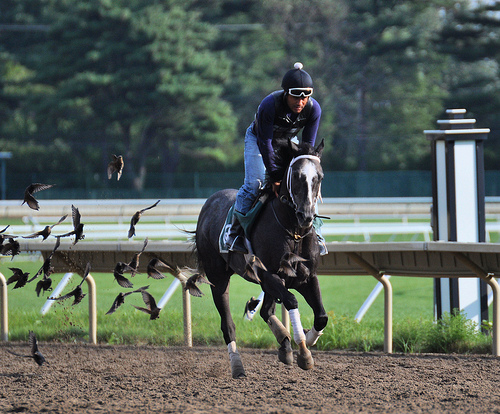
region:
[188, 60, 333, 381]
jockey dressed in blue on dark brown horse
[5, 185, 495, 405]
railings over grass and dirt surfaces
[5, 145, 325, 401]
dark birds flying behind horse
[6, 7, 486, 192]
fence in front of tall green trees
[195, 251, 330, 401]
running legs lifted over ground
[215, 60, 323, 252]
jockey leaning forward supported by arms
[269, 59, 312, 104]
man has black helmet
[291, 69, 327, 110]
man is wearing goggles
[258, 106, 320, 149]
man has purple shirt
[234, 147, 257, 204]
man has grey pants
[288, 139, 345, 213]
white stripe on horse's face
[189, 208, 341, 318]
man on brown horse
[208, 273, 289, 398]
horse has brown legs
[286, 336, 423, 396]
course is dark brown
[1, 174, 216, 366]
birds scatter behind horse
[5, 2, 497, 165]
green leaves on trees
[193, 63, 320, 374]
jockey riding on horse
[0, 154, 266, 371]
flock of flying birds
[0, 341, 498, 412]
dirt surface of race track